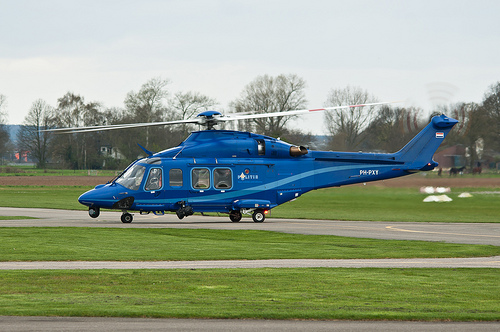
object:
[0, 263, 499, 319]
grass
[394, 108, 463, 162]
tail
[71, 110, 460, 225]
helicopter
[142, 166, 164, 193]
window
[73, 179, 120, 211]
tip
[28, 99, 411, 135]
propeller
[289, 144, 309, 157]
exhaust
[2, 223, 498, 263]
grass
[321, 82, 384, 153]
tree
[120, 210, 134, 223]
landing gear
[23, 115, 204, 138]
rotor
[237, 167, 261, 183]
decal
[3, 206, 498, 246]
asphalt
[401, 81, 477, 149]
rotor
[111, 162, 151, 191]
windshield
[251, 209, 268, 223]
wheel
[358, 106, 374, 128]
branch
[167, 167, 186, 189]
window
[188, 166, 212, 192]
window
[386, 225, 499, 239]
line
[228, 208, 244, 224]
wheel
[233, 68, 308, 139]
tree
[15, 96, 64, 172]
tree